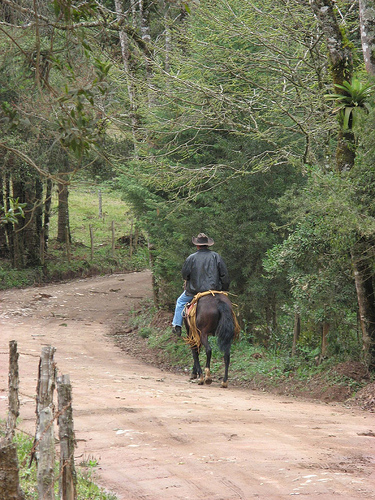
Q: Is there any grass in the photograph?
A: Yes, there is grass.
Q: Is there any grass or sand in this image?
A: Yes, there is grass.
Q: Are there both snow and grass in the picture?
A: No, there is grass but no snow.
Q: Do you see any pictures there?
A: No, there are no pictures.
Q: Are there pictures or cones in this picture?
A: No, there are no pictures or cones.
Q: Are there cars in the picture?
A: No, there are no cars.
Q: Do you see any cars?
A: No, there are no cars.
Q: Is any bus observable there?
A: No, there are no buses.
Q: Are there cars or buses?
A: No, there are no buses or cars.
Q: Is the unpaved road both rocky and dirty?
A: Yes, the road is rocky and dirty.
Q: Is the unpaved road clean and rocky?
A: No, the road is rocky but dirty.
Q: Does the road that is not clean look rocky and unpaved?
A: Yes, the road is rocky and unpaved.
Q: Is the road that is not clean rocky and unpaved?
A: Yes, the road is rocky and unpaved.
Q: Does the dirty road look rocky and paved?
A: No, the road is rocky but unpaved.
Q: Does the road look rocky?
A: Yes, the road is rocky.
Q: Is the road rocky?
A: Yes, the road is rocky.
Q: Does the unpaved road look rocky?
A: Yes, the road is rocky.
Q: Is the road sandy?
A: No, the road is rocky.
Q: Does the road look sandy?
A: No, the road is rocky.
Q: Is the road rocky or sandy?
A: The road is rocky.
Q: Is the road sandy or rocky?
A: The road is rocky.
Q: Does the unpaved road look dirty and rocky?
A: Yes, the road is dirty and rocky.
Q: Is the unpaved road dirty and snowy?
A: No, the road is dirty but rocky.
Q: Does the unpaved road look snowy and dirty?
A: No, the road is dirty but rocky.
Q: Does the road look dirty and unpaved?
A: Yes, the road is dirty and unpaved.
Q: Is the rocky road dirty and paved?
A: No, the road is dirty but unpaved.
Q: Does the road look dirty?
A: Yes, the road is dirty.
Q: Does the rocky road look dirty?
A: Yes, the road is dirty.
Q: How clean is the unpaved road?
A: The road is dirty.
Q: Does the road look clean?
A: No, the road is dirty.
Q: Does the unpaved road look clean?
A: No, the road is dirty.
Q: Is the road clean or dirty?
A: The road is dirty.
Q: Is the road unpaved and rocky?
A: Yes, the road is unpaved and rocky.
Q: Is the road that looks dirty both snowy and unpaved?
A: No, the road is unpaved but rocky.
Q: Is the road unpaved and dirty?
A: Yes, the road is unpaved and dirty.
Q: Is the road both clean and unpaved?
A: No, the road is unpaved but dirty.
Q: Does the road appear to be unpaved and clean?
A: No, the road is unpaved but dirty.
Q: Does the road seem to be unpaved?
A: Yes, the road is unpaved.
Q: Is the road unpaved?
A: Yes, the road is unpaved.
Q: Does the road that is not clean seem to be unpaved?
A: Yes, the road is unpaved.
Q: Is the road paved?
A: No, the road is unpaved.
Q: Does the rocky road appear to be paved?
A: No, the road is unpaved.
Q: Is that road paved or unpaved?
A: The road is unpaved.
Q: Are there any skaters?
A: No, there are no skaters.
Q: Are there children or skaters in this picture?
A: No, there are no skaters or children.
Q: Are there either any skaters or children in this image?
A: No, there are no skaters or children.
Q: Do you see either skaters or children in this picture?
A: No, there are no skaters or children.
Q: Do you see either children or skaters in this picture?
A: No, there are no skaters or children.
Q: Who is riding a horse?
A: The man is riding a horse.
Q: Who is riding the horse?
A: The man is riding a horse.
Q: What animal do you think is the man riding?
A: The man is riding a horse.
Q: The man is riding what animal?
A: The man is riding a horse.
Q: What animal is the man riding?
A: The man is riding a horse.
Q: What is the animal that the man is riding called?
A: The animal is a horse.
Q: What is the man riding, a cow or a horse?
A: The man is riding a horse.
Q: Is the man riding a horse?
A: Yes, the man is riding a horse.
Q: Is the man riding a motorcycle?
A: No, the man is riding a horse.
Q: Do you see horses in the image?
A: Yes, there is a horse.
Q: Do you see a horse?
A: Yes, there is a horse.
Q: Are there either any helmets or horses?
A: Yes, there is a horse.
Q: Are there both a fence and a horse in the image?
A: Yes, there are both a horse and a fence.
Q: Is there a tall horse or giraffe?
A: Yes, there is a tall horse.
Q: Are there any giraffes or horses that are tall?
A: Yes, the horse is tall.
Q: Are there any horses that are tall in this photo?
A: Yes, there is a tall horse.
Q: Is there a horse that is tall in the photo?
A: Yes, there is a tall horse.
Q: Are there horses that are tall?
A: Yes, there is a horse that is tall.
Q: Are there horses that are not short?
A: Yes, there is a tall horse.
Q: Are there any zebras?
A: No, there are no zebras.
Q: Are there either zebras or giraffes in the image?
A: No, there are no zebras or giraffes.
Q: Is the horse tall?
A: Yes, the horse is tall.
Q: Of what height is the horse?
A: The horse is tall.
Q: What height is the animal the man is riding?
A: The horse is tall.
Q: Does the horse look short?
A: No, the horse is tall.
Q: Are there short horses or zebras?
A: No, there is a horse but it is tall.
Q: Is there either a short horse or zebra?
A: No, there is a horse but it is tall.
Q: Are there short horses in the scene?
A: No, there is a horse but it is tall.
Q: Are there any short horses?
A: No, there is a horse but it is tall.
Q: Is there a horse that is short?
A: No, there is a horse but it is tall.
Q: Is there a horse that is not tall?
A: No, there is a horse but it is tall.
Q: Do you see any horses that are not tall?
A: No, there is a horse but it is tall.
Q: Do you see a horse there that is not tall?
A: No, there is a horse but it is tall.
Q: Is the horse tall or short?
A: The horse is tall.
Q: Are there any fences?
A: Yes, there is a fence.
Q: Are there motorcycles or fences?
A: Yes, there is a fence.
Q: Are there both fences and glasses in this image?
A: No, there is a fence but no glasses.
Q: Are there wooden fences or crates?
A: Yes, there is a wood fence.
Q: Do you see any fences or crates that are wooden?
A: Yes, the fence is wooden.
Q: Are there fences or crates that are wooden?
A: Yes, the fence is wooden.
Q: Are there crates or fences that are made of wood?
A: Yes, the fence is made of wood.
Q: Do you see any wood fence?
A: Yes, there is a fence that is made of wood.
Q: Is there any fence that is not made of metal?
A: Yes, there is a fence that is made of wood.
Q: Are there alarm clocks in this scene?
A: No, there are no alarm clocks.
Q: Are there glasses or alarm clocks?
A: No, there are no alarm clocks or glasses.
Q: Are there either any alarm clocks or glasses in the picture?
A: No, there are no alarm clocks or glasses.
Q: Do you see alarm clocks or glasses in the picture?
A: No, there are no alarm clocks or glasses.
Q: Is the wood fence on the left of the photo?
A: Yes, the fence is on the left of the image.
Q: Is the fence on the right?
A: No, the fence is on the left of the image.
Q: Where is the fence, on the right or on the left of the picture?
A: The fence is on the left of the image.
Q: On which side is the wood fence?
A: The fence is on the left of the image.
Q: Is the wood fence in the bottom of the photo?
A: Yes, the fence is in the bottom of the image.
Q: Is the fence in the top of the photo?
A: No, the fence is in the bottom of the image.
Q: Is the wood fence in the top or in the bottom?
A: The fence is in the bottom of the image.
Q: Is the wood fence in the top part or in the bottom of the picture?
A: The fence is in the bottom of the image.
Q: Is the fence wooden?
A: Yes, the fence is wooden.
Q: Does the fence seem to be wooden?
A: Yes, the fence is wooden.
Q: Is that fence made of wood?
A: Yes, the fence is made of wood.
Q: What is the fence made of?
A: The fence is made of wood.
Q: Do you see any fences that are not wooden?
A: No, there is a fence but it is wooden.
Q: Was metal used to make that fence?
A: No, the fence is made of wood.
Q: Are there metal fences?
A: No, there is a fence but it is made of wood.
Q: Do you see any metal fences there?
A: No, there is a fence but it is made of wood.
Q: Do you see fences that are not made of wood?
A: No, there is a fence but it is made of wood.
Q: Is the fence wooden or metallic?
A: The fence is wooden.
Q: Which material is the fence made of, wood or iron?
A: The fence is made of wood.